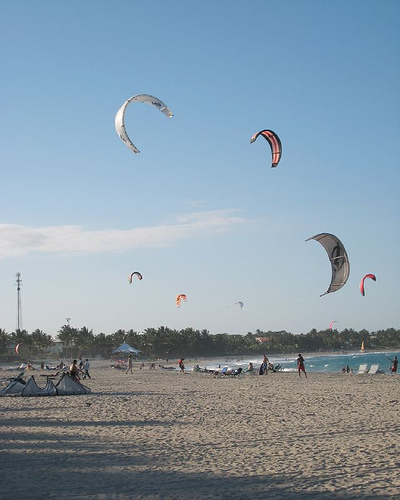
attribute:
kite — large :
[297, 225, 355, 306]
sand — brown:
[6, 400, 387, 498]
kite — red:
[360, 271, 374, 296]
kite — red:
[177, 291, 187, 309]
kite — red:
[327, 319, 339, 332]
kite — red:
[13, 337, 21, 354]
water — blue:
[234, 352, 398, 371]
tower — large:
[12, 273, 21, 333]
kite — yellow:
[174, 290, 186, 304]